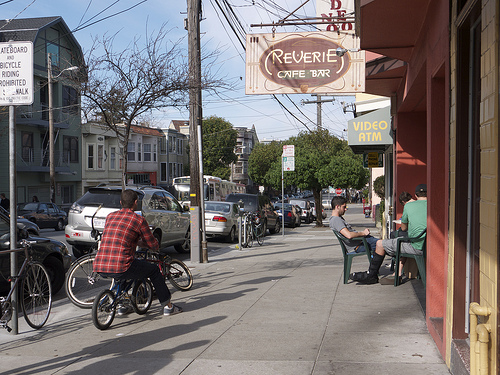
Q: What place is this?
A: It is a sidewalk.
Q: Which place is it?
A: It is a sidewalk.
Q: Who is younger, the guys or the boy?
A: The boy is younger than the guys.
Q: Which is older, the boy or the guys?
A: The guys is older than the boy.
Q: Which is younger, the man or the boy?
A: The boy is younger than the man.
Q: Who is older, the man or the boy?
A: The man is older than the boy.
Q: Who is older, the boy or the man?
A: The man is older than the boy.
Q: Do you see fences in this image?
A: No, there are no fences.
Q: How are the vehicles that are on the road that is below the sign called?
A: The vehicles are cars.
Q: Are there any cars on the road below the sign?
A: Yes, there are cars on the road.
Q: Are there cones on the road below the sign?
A: No, there are cars on the road.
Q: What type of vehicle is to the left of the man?
A: The vehicles are cars.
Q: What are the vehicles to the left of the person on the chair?
A: The vehicles are cars.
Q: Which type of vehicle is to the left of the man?
A: The vehicles are cars.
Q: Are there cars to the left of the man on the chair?
A: Yes, there are cars to the left of the man.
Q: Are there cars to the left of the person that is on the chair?
A: Yes, there are cars to the left of the man.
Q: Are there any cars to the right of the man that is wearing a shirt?
A: No, the cars are to the left of the man.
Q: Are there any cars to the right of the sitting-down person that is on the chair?
A: No, the cars are to the left of the man.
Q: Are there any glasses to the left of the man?
A: No, there are cars to the left of the man.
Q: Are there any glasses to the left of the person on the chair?
A: No, there are cars to the left of the man.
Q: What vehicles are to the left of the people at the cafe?
A: The vehicles are cars.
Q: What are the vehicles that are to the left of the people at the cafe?
A: The vehicles are cars.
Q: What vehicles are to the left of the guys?
A: The vehicles are cars.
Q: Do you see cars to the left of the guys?
A: Yes, there are cars to the left of the guys.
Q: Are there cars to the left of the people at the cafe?
A: Yes, there are cars to the left of the guys.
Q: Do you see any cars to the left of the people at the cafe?
A: Yes, there are cars to the left of the guys.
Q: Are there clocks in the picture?
A: No, there are no clocks.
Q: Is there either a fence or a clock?
A: No, there are no clocks or fences.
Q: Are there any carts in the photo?
A: No, there are no carts.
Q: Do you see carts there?
A: No, there are no carts.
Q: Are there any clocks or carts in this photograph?
A: No, there are no carts or clocks.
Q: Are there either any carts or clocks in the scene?
A: No, there are no carts or clocks.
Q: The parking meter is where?
A: The parking meter is on the sidewalk.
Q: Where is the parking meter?
A: The parking meter is on the sidewalk.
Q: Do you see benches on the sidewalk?
A: No, there is a parking meter on the sidewalk.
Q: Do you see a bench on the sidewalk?
A: No, there is a parking meter on the sidewalk.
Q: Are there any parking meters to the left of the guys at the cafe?
A: Yes, there is a parking meter to the left of the guys.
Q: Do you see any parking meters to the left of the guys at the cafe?
A: Yes, there is a parking meter to the left of the guys.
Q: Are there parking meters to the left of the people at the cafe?
A: Yes, there is a parking meter to the left of the guys.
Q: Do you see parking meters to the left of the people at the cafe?
A: Yes, there is a parking meter to the left of the guys.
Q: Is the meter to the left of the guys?
A: Yes, the meter is to the left of the guys.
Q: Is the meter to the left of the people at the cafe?
A: Yes, the meter is to the left of the guys.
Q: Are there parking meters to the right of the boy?
A: Yes, there is a parking meter to the right of the boy.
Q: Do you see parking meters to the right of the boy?
A: Yes, there is a parking meter to the right of the boy.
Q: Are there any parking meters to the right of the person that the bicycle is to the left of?
A: Yes, there is a parking meter to the right of the boy.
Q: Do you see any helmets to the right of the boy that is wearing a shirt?
A: No, there is a parking meter to the right of the boy.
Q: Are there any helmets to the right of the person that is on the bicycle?
A: No, there is a parking meter to the right of the boy.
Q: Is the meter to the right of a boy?
A: Yes, the meter is to the right of a boy.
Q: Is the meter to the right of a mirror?
A: No, the meter is to the right of a boy.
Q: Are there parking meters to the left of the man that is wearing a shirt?
A: Yes, there is a parking meter to the left of the man.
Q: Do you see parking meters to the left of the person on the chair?
A: Yes, there is a parking meter to the left of the man.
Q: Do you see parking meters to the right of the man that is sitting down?
A: No, the parking meter is to the left of the man.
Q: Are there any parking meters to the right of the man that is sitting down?
A: No, the parking meter is to the left of the man.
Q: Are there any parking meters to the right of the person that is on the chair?
A: No, the parking meter is to the left of the man.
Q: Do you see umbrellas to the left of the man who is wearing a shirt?
A: No, there is a parking meter to the left of the man.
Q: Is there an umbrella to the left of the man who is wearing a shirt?
A: No, there is a parking meter to the left of the man.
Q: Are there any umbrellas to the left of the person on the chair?
A: No, there is a parking meter to the left of the man.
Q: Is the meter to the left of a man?
A: Yes, the meter is to the left of a man.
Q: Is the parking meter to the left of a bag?
A: No, the parking meter is to the left of a man.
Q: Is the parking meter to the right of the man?
A: No, the parking meter is to the left of the man.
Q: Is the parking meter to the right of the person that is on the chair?
A: No, the parking meter is to the left of the man.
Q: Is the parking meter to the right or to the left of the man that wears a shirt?
A: The parking meter is to the left of the man.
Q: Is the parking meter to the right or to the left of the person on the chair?
A: The parking meter is to the left of the man.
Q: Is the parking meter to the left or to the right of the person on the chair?
A: The parking meter is to the left of the man.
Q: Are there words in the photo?
A: Yes, there are words.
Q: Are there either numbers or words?
A: Yes, there are words.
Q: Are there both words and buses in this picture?
A: Yes, there are both words and a bus.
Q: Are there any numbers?
A: No, there are no numbers.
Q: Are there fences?
A: No, there are no fences.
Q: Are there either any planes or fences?
A: No, there are no fences or planes.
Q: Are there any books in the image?
A: No, there are no books.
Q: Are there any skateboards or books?
A: No, there are no books or skateboards.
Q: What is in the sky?
A: The wires are in the sky.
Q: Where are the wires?
A: The wires are in the sky.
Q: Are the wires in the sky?
A: Yes, the wires are in the sky.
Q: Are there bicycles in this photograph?
A: Yes, there is a bicycle.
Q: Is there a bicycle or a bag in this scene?
A: Yes, there is a bicycle.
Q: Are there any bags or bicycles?
A: Yes, there is a bicycle.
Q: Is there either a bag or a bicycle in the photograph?
A: Yes, there is a bicycle.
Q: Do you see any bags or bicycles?
A: Yes, there is a bicycle.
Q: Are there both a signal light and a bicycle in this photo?
A: No, there is a bicycle but no traffic lights.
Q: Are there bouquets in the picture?
A: No, there are no bouquets.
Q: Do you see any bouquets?
A: No, there are no bouquets.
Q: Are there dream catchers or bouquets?
A: No, there are no bouquets or dream catchers.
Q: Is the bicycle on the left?
A: Yes, the bicycle is on the left of the image.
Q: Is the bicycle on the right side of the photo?
A: No, the bicycle is on the left of the image.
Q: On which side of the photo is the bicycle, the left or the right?
A: The bicycle is on the left of the image.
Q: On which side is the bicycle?
A: The bicycle is on the left of the image.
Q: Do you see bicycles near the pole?
A: Yes, there is a bicycle near the pole.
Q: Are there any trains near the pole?
A: No, there is a bicycle near the pole.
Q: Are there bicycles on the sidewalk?
A: Yes, there is a bicycle on the sidewalk.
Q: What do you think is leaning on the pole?
A: The bicycle is leaning on the pole.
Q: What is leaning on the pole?
A: The bicycle is leaning on the pole.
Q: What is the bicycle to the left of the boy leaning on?
A: The bicycle is leaning on the pole.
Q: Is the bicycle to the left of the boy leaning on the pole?
A: Yes, the bicycle is leaning on the pole.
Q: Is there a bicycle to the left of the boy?
A: Yes, there is a bicycle to the left of the boy.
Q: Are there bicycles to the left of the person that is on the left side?
A: Yes, there is a bicycle to the left of the boy.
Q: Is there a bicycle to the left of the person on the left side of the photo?
A: Yes, there is a bicycle to the left of the boy.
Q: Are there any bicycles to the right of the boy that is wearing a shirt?
A: No, the bicycle is to the left of the boy.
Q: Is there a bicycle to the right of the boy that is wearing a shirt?
A: No, the bicycle is to the left of the boy.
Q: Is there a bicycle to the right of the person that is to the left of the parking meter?
A: No, the bicycle is to the left of the boy.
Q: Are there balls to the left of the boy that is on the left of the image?
A: No, there is a bicycle to the left of the boy.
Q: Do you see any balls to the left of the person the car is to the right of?
A: No, there is a bicycle to the left of the boy.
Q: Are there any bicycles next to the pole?
A: Yes, there is a bicycle next to the pole.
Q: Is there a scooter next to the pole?
A: No, there is a bicycle next to the pole.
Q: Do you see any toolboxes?
A: No, there are no toolboxes.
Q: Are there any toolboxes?
A: No, there are no toolboxes.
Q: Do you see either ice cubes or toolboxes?
A: No, there are no toolboxes or ice cubes.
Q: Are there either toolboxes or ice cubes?
A: No, there are no toolboxes or ice cubes.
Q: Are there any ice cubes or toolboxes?
A: No, there are no toolboxes or ice cubes.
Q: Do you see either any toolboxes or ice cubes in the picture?
A: No, there are no toolboxes or ice cubes.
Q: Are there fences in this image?
A: No, there are no fences.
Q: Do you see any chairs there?
A: Yes, there is a chair.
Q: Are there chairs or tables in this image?
A: Yes, there is a chair.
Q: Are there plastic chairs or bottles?
A: Yes, there is a plastic chair.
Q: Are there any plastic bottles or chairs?
A: Yes, there is a plastic chair.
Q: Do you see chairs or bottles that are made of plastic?
A: Yes, the chair is made of plastic.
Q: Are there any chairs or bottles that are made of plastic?
A: Yes, the chair is made of plastic.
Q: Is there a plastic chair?
A: Yes, there is a chair that is made of plastic.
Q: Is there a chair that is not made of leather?
A: Yes, there is a chair that is made of plastic.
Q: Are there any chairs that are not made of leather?
A: Yes, there is a chair that is made of plastic.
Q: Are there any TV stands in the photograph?
A: No, there are no TV stands.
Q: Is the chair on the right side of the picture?
A: Yes, the chair is on the right of the image.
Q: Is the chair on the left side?
A: No, the chair is on the right of the image.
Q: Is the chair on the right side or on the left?
A: The chair is on the right of the image.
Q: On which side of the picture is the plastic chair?
A: The chair is on the right of the image.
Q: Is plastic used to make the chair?
A: Yes, the chair is made of plastic.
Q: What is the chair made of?
A: The chair is made of plastic.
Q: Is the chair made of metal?
A: No, the chair is made of plastic.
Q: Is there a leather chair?
A: No, there is a chair but it is made of plastic.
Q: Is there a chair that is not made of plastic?
A: No, there is a chair but it is made of plastic.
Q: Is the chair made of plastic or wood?
A: The chair is made of plastic.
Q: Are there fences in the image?
A: No, there are no fences.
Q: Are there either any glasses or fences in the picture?
A: No, there are no fences or glasses.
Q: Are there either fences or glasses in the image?
A: No, there are no fences or glasses.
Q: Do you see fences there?
A: No, there are no fences.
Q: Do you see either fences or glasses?
A: No, there are no fences or glasses.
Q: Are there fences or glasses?
A: No, there are no fences or glasses.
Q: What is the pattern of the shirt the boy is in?
A: The shirt is striped.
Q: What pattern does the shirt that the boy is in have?
A: The shirt has striped pattern.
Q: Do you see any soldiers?
A: No, there are no soldiers.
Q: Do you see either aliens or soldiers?
A: No, there are no soldiers or aliens.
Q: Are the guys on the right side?
A: Yes, the guys are on the right of the image.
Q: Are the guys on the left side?
A: No, the guys are on the right of the image.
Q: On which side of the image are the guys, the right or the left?
A: The guys are on the right of the image.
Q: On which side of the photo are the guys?
A: The guys are on the right of the image.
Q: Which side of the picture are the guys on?
A: The guys are on the right of the image.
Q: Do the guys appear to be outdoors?
A: Yes, the guys are outdoors.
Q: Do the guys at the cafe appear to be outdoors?
A: Yes, the guys are outdoors.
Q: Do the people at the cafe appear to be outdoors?
A: Yes, the guys are outdoors.